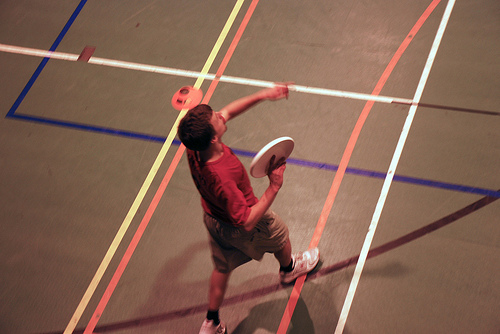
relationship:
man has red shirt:
[176, 81, 317, 331] [187, 145, 259, 227]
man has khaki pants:
[176, 81, 317, 331] [199, 212, 290, 272]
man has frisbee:
[176, 81, 317, 331] [245, 134, 295, 184]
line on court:
[45, 22, 499, 333] [9, 13, 484, 325]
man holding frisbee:
[176, 81, 317, 331] [240, 135, 292, 186]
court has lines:
[9, 13, 484, 325] [372, 10, 449, 88]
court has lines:
[9, 13, 484, 325] [287, 94, 440, 266]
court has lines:
[9, 13, 484, 325] [181, 8, 268, 105]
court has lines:
[9, 13, 484, 325] [12, 14, 154, 164]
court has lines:
[9, 13, 484, 325] [51, 109, 187, 331]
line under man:
[400, 165, 451, 191] [176, 81, 317, 331]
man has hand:
[176, 81, 317, 331] [266, 153, 286, 185]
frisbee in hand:
[250, 136, 295, 178] [266, 153, 286, 185]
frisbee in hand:
[249, 134, 293, 174] [267, 157, 287, 187]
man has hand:
[176, 81, 317, 331] [267, 157, 287, 187]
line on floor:
[45, 22, 499, 333] [5, 14, 482, 329]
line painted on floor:
[45, 22, 499, 333] [319, 41, 499, 269]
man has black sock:
[176, 81, 317, 331] [278, 258, 297, 273]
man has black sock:
[176, 81, 317, 331] [205, 307, 221, 322]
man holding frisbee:
[176, 81, 317, 331] [249, 135, 294, 182]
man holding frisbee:
[153, 80, 326, 332] [246, 127, 300, 177]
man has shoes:
[153, 80, 326, 332] [272, 246, 325, 288]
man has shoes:
[153, 80, 326, 332] [180, 312, 235, 332]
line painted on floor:
[45, 22, 499, 333] [5, 5, 483, 329]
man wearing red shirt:
[176, 81, 317, 331] [186, 141, 259, 228]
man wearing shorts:
[176, 81, 317, 331] [204, 208, 293, 274]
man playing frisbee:
[176, 81, 317, 331] [244, 147, 315, 186]